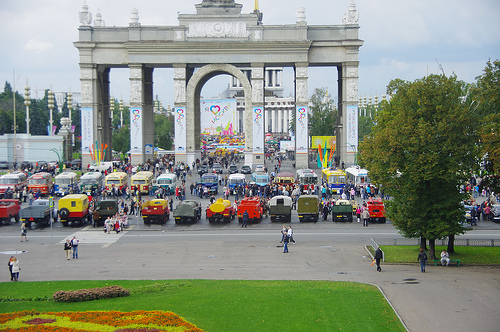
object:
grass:
[0, 279, 406, 331]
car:
[58, 194, 89, 227]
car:
[205, 197, 236, 224]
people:
[5, 138, 375, 210]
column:
[337, 62, 359, 171]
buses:
[0, 171, 53, 197]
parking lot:
[0, 163, 497, 229]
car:
[234, 194, 263, 223]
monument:
[74, 0, 363, 172]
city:
[0, 0, 499, 332]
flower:
[87, 291, 93, 293]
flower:
[102, 286, 104, 289]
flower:
[88, 285, 93, 287]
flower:
[74, 292, 81, 296]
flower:
[59, 287, 66, 294]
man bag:
[371, 259, 376, 266]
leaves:
[357, 81, 461, 195]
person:
[440, 249, 450, 267]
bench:
[433, 259, 461, 267]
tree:
[355, 59, 479, 259]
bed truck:
[18, 200, 58, 228]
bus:
[152, 174, 177, 195]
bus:
[130, 171, 153, 194]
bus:
[104, 172, 128, 196]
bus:
[80, 172, 104, 193]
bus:
[54, 172, 77, 197]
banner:
[80, 105, 361, 157]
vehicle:
[297, 195, 319, 222]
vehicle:
[268, 196, 293, 223]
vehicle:
[172, 200, 203, 225]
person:
[374, 246, 384, 272]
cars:
[0, 199, 22, 226]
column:
[291, 62, 311, 171]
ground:
[0, 224, 500, 330]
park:
[0, 0, 498, 329]